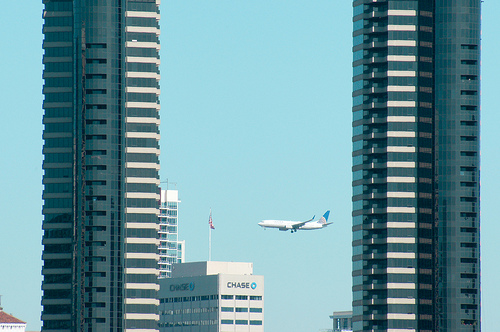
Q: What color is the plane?
A: White.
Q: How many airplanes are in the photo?
A: One.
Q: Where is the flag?
A: On top of the Chase building.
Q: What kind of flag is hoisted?
A: The American flag.